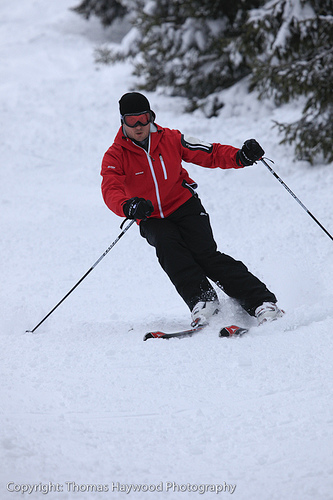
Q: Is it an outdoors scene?
A: Yes, it is outdoors.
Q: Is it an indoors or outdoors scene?
A: It is outdoors.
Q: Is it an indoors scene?
A: No, it is outdoors.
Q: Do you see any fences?
A: No, there are no fences.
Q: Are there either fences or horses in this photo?
A: No, there are no fences or horses.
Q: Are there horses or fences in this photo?
A: No, there are no fences or horses.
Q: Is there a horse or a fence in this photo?
A: No, there are no fences or horses.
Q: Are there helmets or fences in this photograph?
A: No, there are no fences or helmets.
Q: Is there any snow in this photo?
A: Yes, there is snow.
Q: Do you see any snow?
A: Yes, there is snow.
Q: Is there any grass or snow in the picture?
A: Yes, there is snow.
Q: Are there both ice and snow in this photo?
A: No, there is snow but no ice.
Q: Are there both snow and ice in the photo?
A: No, there is snow but no ice.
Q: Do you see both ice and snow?
A: No, there is snow but no ice.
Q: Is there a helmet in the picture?
A: No, there are no helmets.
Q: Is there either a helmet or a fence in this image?
A: No, there are no helmets or fences.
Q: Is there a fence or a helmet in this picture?
A: No, there are no helmets or fences.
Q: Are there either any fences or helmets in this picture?
A: No, there are no helmets or fences.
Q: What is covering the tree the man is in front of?
A: The snow is covering the tree.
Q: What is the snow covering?
A: The snow is covering the tree.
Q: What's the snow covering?
A: The snow is covering the tree.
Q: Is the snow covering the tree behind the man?
A: Yes, the snow is covering the tree.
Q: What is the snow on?
A: The snow is on the tree.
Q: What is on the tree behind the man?
A: The snow is on the tree.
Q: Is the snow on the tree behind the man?
A: Yes, the snow is on the tree.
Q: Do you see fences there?
A: No, there are no fences.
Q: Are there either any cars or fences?
A: No, there are no fences or cars.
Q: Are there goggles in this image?
A: Yes, there are goggles.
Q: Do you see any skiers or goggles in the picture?
A: Yes, there are goggles.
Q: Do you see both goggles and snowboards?
A: No, there are goggles but no snowboards.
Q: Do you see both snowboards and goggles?
A: No, there are goggles but no snowboards.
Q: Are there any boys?
A: No, there are no boys.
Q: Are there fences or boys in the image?
A: No, there are no boys or fences.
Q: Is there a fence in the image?
A: No, there are no fences.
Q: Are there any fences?
A: No, there are no fences.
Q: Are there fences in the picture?
A: No, there are no fences.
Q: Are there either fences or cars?
A: No, there are no fences or cars.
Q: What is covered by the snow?
A: The tree is covered by the snow.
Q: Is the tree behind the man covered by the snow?
A: Yes, the tree is covered by the snow.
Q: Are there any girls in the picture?
A: No, there are no girls.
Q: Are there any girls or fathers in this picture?
A: No, there are no girls or fathers.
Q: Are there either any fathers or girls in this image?
A: No, there are no girls or fathers.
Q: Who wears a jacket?
A: The man wears a jacket.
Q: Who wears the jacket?
A: The man wears a jacket.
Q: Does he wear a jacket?
A: Yes, the man wears a jacket.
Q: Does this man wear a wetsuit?
A: No, the man wears a jacket.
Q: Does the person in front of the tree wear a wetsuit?
A: No, the man wears a jacket.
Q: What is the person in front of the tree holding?
A: The man is holding the pole.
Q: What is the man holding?
A: The man is holding the pole.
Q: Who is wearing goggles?
A: The man is wearing goggles.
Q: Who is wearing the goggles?
A: The man is wearing goggles.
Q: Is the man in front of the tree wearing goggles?
A: Yes, the man is wearing goggles.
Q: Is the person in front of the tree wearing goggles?
A: Yes, the man is wearing goggles.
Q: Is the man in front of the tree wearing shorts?
A: No, the man is wearing goggles.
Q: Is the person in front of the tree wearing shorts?
A: No, the man is wearing goggles.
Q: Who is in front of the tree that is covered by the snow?
A: The man is in front of the tree.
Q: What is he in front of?
A: The man is in front of the tree.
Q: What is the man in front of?
A: The man is in front of the tree.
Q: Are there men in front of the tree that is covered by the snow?
A: Yes, there is a man in front of the tree.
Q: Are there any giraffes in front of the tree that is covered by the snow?
A: No, there is a man in front of the tree.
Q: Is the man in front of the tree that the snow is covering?
A: Yes, the man is in front of the tree.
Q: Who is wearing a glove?
A: The man is wearing a glove.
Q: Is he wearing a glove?
A: Yes, the man is wearing a glove.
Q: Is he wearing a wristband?
A: No, the man is wearing a glove.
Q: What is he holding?
A: The man is holding the pole.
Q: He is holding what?
A: The man is holding the pole.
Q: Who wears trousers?
A: The man wears trousers.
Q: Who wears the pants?
A: The man wears trousers.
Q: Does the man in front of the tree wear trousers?
A: Yes, the man wears trousers.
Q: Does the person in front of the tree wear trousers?
A: Yes, the man wears trousers.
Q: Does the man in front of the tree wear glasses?
A: No, the man wears trousers.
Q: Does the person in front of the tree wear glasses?
A: No, the man wears trousers.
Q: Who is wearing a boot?
A: The man is wearing a boot.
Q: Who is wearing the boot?
A: The man is wearing a boot.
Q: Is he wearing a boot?
A: Yes, the man is wearing a boot.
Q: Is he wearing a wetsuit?
A: No, the man is wearing a boot.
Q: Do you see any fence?
A: No, there are no fences.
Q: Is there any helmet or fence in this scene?
A: No, there are no fences or helmets.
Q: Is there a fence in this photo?
A: No, there are no fences.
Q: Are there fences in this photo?
A: No, there are no fences.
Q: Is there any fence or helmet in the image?
A: No, there are no fences or helmets.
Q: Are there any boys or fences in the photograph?
A: No, there are no fences or boys.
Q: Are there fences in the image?
A: No, there are no fences.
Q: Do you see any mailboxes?
A: No, there are no mailboxes.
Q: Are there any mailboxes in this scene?
A: No, there are no mailboxes.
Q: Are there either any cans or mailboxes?
A: No, there are no mailboxes or cans.